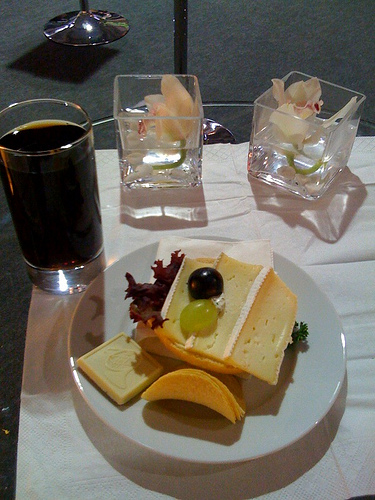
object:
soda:
[0, 120, 107, 264]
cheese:
[133, 252, 298, 385]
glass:
[114, 73, 203, 189]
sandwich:
[128, 253, 299, 389]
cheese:
[76, 332, 164, 407]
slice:
[229, 274, 301, 386]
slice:
[189, 255, 257, 357]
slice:
[152, 256, 215, 340]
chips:
[139, 364, 248, 423]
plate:
[67, 232, 348, 468]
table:
[0, 0, 373, 499]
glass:
[1, 95, 103, 294]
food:
[75, 248, 310, 425]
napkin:
[15, 136, 374, 499]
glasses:
[0, 96, 106, 294]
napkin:
[154, 230, 276, 277]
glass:
[248, 69, 367, 198]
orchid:
[269, 76, 356, 175]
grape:
[181, 299, 218, 333]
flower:
[121, 76, 196, 187]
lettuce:
[124, 247, 182, 330]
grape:
[189, 264, 229, 296]